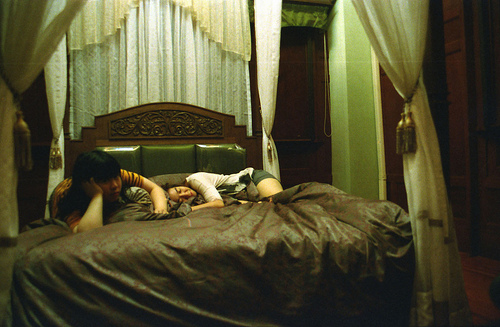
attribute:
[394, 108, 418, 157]
tassel — golden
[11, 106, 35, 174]
tassel — golden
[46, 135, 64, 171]
tassel — golden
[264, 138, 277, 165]
tassel — golden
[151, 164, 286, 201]
woman — young, lying down, asian, sleeping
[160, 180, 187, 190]
hair — black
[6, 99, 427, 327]
bed — queen sized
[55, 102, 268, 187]
headboard — wooden, brown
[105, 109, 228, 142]
design — wooden, ornate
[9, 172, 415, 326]
comforter — brown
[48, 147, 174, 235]
guy — lying down, asian, young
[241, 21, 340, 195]
door — wooden, brown, large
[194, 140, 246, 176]
cushion — green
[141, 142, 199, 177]
cushion — green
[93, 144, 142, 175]
cushion — green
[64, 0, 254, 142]
curtain — white, sheer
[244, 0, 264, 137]
post — wooden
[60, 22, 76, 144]
post — wooden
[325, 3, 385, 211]
wall — green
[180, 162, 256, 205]
shirt — white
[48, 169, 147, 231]
shirt — orange, black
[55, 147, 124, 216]
hair — black